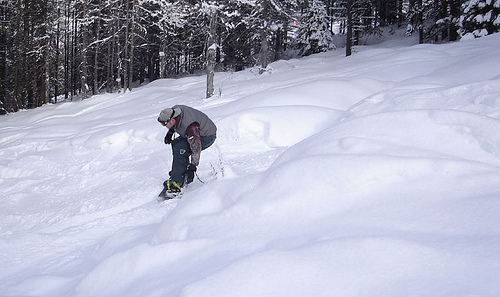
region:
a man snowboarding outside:
[47, 43, 414, 286]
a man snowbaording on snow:
[104, 98, 350, 290]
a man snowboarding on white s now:
[102, 66, 297, 260]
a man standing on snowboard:
[87, 69, 333, 289]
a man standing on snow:
[126, 75, 272, 293]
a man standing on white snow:
[97, 76, 308, 278]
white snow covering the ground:
[54, 64, 434, 294]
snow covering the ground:
[29, 70, 499, 273]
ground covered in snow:
[47, 91, 444, 288]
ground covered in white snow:
[79, 97, 384, 289]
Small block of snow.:
[322, 133, 370, 154]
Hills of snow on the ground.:
[275, 185, 425, 252]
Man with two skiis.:
[161, 186, 206, 203]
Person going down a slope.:
[145, 91, 229, 205]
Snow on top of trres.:
[28, 21, 116, 52]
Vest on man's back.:
[172, 103, 220, 141]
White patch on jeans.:
[177, 148, 195, 168]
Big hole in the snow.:
[255, 92, 339, 169]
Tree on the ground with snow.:
[422, 3, 490, 37]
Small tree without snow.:
[18, 36, 48, 117]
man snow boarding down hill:
[132, 88, 227, 233]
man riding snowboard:
[135, 83, 237, 220]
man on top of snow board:
[95, 80, 250, 212]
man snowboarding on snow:
[137, 86, 225, 248]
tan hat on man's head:
[160, 103, 181, 125]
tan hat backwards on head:
[157, 103, 180, 124]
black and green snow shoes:
[161, 174, 183, 200]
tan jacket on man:
[175, 105, 213, 140]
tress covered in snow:
[20, 10, 133, 85]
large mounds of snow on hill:
[218, 56, 437, 273]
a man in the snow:
[151, 76, 238, 203]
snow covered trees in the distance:
[5, 0, 497, 111]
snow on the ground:
[7, 41, 497, 292]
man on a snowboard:
[147, 99, 237, 211]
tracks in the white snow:
[11, 135, 243, 269]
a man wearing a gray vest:
[170, 103, 218, 144]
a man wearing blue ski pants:
[170, 136, 217, 187]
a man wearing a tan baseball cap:
[155, 106, 182, 123]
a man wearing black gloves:
[160, 129, 200, 191]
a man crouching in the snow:
[145, 102, 230, 209]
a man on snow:
[153, 101, 218, 201]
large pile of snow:
[2, 7, 497, 292]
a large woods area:
[0, 0, 499, 111]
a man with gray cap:
[155, 102, 180, 123]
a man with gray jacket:
[172, 100, 213, 140]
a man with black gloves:
[161, 126, 193, 181]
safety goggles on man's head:
[155, 105, 175, 125]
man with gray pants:
[166, 126, 216, 186]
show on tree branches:
[2, 1, 499, 113]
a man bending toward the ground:
[158, 101, 218, 202]